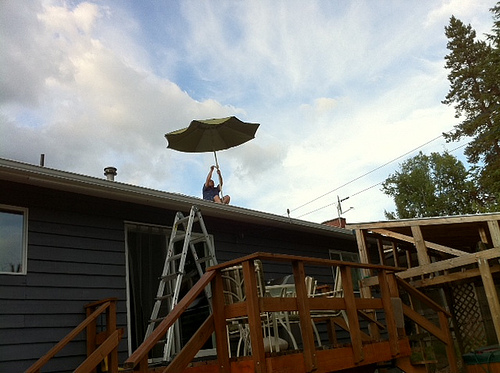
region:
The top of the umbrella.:
[156, 117, 258, 148]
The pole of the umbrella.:
[207, 145, 222, 179]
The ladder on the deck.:
[147, 214, 229, 361]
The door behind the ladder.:
[129, 227, 216, 361]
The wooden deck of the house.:
[26, 250, 407, 371]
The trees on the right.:
[373, 13, 495, 208]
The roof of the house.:
[10, 153, 348, 233]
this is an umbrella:
[146, 85, 260, 185]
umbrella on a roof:
[0, 77, 363, 262]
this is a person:
[197, 162, 237, 219]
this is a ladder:
[113, 189, 256, 367]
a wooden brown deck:
[41, 206, 482, 371]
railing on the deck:
[181, 250, 410, 344]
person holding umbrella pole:
[185, 150, 232, 200]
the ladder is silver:
[132, 182, 268, 371]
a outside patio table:
[191, 215, 368, 357]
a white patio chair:
[267, 244, 373, 342]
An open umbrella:
[161, 111, 254, 203]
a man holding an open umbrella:
[161, 115, 264, 209]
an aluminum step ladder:
[131, 203, 255, 363]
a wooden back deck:
[70, 252, 472, 369]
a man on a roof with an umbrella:
[5, 113, 381, 243]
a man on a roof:
[8, 163, 359, 238]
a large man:
[197, 163, 247, 210]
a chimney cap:
[96, 160, 123, 180]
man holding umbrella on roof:
[158, 108, 264, 205]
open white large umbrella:
[159, 113, 262, 153]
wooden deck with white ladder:
[35, 242, 469, 372]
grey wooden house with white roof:
[7, 150, 421, 368]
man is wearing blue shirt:
[201, 185, 216, 201]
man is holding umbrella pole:
[198, 140, 228, 210]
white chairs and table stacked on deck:
[220, 263, 360, 340]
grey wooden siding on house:
[3, 180, 407, 360]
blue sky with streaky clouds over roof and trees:
[7, 5, 494, 235]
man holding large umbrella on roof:
[163, 101, 261, 211]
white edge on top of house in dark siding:
[5, 152, 388, 364]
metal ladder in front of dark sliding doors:
[113, 201, 243, 363]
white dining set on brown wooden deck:
[27, 250, 459, 368]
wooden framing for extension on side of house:
[323, 215, 495, 360]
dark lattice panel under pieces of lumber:
[432, 258, 497, 363]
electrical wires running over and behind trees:
[280, 15, 495, 229]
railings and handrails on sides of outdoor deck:
[29, 249, 461, 362]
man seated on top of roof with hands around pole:
[200, 161, 232, 213]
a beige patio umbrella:
[164, 105, 261, 150]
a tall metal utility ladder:
[141, 203, 226, 360]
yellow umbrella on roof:
[153, 106, 254, 156]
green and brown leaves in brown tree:
[385, 148, 452, 203]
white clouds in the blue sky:
[60, 43, 135, 94]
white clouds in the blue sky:
[280, 97, 335, 138]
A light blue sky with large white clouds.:
[0, 3, 497, 204]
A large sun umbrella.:
[160, 113, 263, 158]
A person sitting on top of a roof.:
[194, 159, 236, 211]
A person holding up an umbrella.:
[156, 95, 271, 216]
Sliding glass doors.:
[122, 223, 219, 364]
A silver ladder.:
[134, 204, 243, 364]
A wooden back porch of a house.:
[32, 218, 469, 371]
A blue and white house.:
[1, 153, 392, 370]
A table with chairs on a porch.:
[205, 255, 364, 354]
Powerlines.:
[270, 118, 497, 226]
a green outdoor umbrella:
[165, 111, 263, 156]